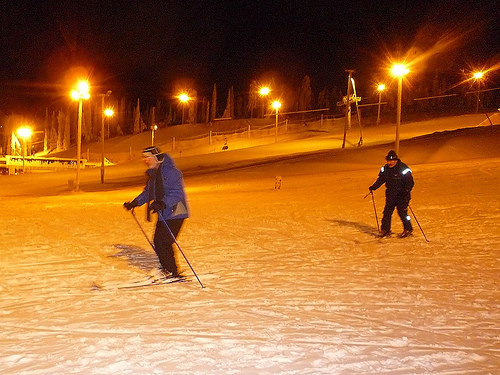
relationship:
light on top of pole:
[65, 81, 92, 103] [75, 105, 81, 191]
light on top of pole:
[176, 91, 189, 104] [182, 105, 184, 145]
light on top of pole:
[258, 88, 282, 111] [275, 109, 279, 139]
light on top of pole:
[384, 57, 409, 81] [393, 82, 402, 152]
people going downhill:
[122, 146, 189, 283] [97, 272, 499, 361]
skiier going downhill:
[371, 151, 414, 236] [97, 272, 499, 361]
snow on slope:
[86, 281, 495, 351] [97, 272, 499, 361]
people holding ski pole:
[122, 146, 189, 283] [156, 216, 208, 288]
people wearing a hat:
[122, 146, 189, 283] [144, 143, 165, 167]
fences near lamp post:
[171, 122, 272, 145] [272, 115, 282, 142]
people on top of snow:
[122, 146, 189, 283] [86, 281, 495, 351]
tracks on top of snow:
[231, 225, 341, 354] [86, 281, 495, 351]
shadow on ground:
[324, 213, 377, 234] [271, 219, 389, 285]